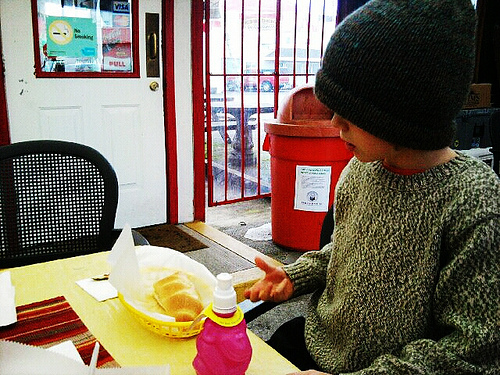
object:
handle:
[144, 9, 159, 84]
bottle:
[174, 277, 291, 369]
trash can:
[266, 85, 354, 248]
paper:
[101, 224, 216, 324]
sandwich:
[146, 264, 206, 326]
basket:
[86, 209, 253, 343]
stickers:
[41, 10, 137, 78]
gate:
[198, 14, 268, 159]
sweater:
[282, 153, 498, 372]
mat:
[0, 294, 123, 374]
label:
[282, 153, 339, 234]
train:
[109, 240, 217, 343]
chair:
[4, 135, 130, 267]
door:
[9, 0, 174, 215]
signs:
[37, 0, 154, 77]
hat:
[306, 3, 494, 161]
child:
[233, 3, 498, 366]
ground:
[403, 67, 446, 121]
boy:
[281, 21, 498, 373]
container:
[181, 263, 262, 374]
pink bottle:
[191, 267, 253, 373]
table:
[1, 242, 301, 374]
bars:
[207, 4, 334, 208]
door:
[196, 0, 341, 221]